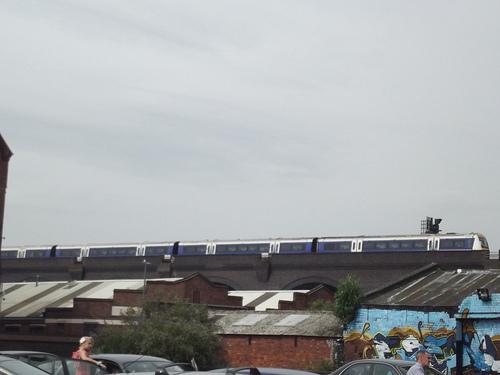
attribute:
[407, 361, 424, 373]
shirt — gray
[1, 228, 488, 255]
train — white , blue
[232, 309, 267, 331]
square — white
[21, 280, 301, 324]
roof — white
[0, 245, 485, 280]
bridge — black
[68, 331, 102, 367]
woman — standing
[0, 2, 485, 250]
sky — cloudy, gray, overcast